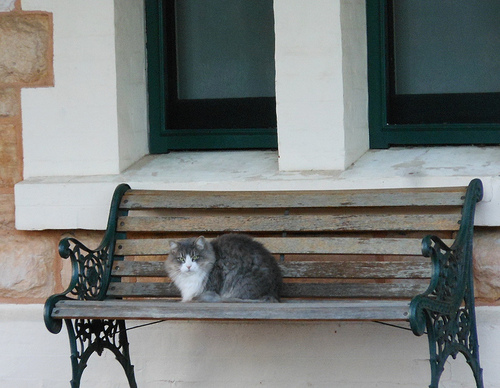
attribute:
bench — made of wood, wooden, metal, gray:
[43, 179, 484, 385]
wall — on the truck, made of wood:
[4, 3, 494, 388]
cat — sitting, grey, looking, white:
[162, 238, 282, 305]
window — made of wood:
[152, 2, 499, 157]